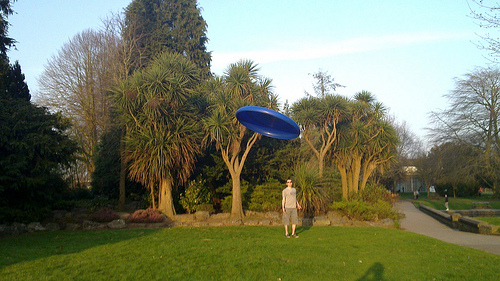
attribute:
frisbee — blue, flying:
[236, 106, 300, 140]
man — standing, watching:
[281, 178, 302, 239]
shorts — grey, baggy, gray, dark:
[283, 207, 298, 225]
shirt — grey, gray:
[281, 187, 297, 208]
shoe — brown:
[284, 232, 291, 238]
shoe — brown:
[291, 233, 299, 237]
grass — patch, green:
[1, 192, 499, 280]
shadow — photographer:
[358, 261, 384, 280]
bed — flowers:
[40, 212, 84, 230]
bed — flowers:
[87, 207, 121, 222]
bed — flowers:
[128, 207, 164, 223]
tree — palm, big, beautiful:
[109, 51, 209, 215]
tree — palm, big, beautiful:
[200, 59, 279, 218]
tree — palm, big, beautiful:
[290, 94, 354, 182]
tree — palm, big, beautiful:
[336, 90, 399, 200]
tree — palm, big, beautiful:
[290, 161, 330, 215]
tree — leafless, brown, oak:
[34, 27, 122, 188]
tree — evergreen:
[0, 0, 90, 223]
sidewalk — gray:
[391, 198, 499, 257]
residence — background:
[390, 159, 448, 193]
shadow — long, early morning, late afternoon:
[0, 229, 164, 269]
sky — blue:
[0, 0, 499, 175]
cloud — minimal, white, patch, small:
[210, 36, 465, 70]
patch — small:
[0, 225, 499, 280]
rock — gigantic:
[107, 218, 127, 229]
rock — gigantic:
[195, 209, 210, 219]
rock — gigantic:
[314, 215, 332, 226]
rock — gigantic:
[210, 212, 231, 219]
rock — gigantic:
[26, 220, 47, 231]